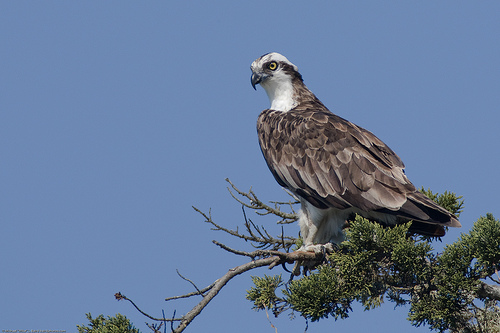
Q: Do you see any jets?
A: No, there are no jets.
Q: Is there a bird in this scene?
A: Yes, there is a bird.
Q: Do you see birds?
A: Yes, there is a bird.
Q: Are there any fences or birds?
A: Yes, there is a bird.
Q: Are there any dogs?
A: No, there are no dogs.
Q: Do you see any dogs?
A: No, there are no dogs.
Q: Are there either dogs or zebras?
A: No, there are no dogs or zebras.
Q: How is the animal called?
A: The animal is a bird.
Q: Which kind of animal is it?
A: The animal is a bird.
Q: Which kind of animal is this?
A: This is a bird.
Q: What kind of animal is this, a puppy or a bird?
A: This is a bird.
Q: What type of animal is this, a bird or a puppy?
A: This is a bird.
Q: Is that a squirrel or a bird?
A: That is a bird.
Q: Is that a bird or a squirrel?
A: That is a bird.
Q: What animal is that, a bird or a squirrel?
A: That is a bird.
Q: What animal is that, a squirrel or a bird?
A: That is a bird.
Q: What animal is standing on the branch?
A: The bird is standing on the branch.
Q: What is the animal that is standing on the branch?
A: The animal is a bird.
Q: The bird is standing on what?
A: The bird is standing on the branch.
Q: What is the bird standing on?
A: The bird is standing on the branch.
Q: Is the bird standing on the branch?
A: Yes, the bird is standing on the branch.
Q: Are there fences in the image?
A: No, there are no fences.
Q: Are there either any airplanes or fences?
A: No, there are no fences or airplanes.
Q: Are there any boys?
A: No, there are no boys.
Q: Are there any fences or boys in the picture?
A: No, there are no boys or fences.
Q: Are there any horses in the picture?
A: No, there are no horses.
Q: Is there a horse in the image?
A: No, there are no horses.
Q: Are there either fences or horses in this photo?
A: No, there are no horses or fences.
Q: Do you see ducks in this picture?
A: No, there are no ducks.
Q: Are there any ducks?
A: No, there are no ducks.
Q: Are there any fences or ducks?
A: No, there are no ducks or fences.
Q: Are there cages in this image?
A: No, there are no cages.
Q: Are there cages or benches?
A: No, there are no cages or benches.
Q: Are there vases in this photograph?
A: No, there are no vases.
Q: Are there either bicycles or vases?
A: No, there are no vases or bicycles.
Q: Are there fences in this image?
A: No, there are no fences.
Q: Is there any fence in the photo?
A: No, there are no fences.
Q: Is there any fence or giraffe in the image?
A: No, there are no fences or giraffes.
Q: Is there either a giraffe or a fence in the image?
A: No, there are no fences or giraffes.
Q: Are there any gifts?
A: No, there are no gifts.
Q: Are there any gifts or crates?
A: No, there are no gifts or crates.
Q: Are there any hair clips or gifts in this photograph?
A: No, there are no gifts or hair clips.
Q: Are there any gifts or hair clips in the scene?
A: No, there are no gifts or hair clips.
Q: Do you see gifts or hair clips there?
A: No, there are no gifts or hair clips.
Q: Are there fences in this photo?
A: No, there are no fences.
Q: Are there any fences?
A: No, there are no fences.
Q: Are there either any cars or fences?
A: No, there are no fences or cars.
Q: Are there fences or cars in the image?
A: No, there are no fences or cars.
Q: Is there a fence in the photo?
A: No, there are no fences.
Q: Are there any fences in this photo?
A: No, there are no fences.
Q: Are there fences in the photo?
A: No, there are no fences.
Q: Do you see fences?
A: No, there are no fences.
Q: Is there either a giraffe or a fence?
A: No, there are no fences or giraffes.